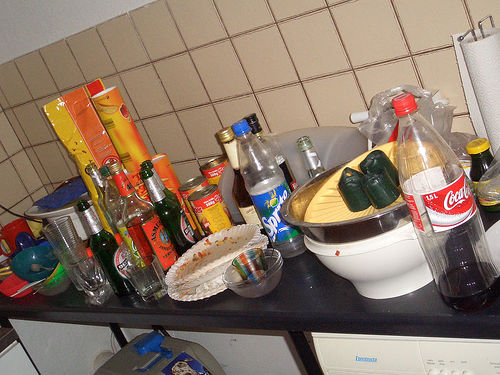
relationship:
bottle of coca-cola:
[393, 94, 500, 307] [422, 173, 478, 233]